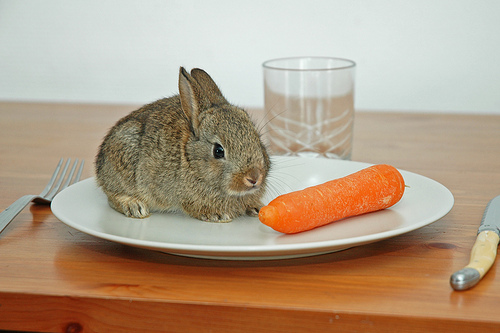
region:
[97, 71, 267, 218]
tiny rabbit on plate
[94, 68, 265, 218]
cute little rabbit on plae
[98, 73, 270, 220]
a really small rabbit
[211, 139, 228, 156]
eye of a rabbit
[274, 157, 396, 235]
a piece of carrot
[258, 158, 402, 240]
carrot on a plate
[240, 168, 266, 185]
nose of a rabbit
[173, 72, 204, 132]
right ear of a rabbit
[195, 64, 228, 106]
left ear of rabbit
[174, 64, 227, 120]
ears of a rabbit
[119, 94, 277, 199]
small bunny on white plate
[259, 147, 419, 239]
small orange carrot on plate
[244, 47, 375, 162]
glass near plate on table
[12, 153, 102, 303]
silver fork on wood table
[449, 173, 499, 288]
silver knife on table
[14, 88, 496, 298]
rectangle wooden table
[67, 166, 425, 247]
shadow on plate cast from bunny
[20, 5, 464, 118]
white wall in background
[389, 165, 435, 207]
small stem of carrot on right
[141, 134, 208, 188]
small brown fur of bunny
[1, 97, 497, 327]
wooden table top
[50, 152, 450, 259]
round white ceramic plate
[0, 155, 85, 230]
silver fork next to plate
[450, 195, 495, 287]
silver knife next to plate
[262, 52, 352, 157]
clear etched glass behind plate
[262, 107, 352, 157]
etching on clear glass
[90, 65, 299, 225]
small brown bunny on plate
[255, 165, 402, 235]
orange carrot on plate next to bunny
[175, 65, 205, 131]
left ear on bunny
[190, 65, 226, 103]
right ear on bunny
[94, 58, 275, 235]
This is a rabbit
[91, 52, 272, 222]
This is a brown rabbit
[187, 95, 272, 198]
Head of a rabbit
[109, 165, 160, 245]
Leg of a rabbit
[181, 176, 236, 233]
Leg of a rabbit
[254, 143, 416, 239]
A piece of carrot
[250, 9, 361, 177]
A grass of water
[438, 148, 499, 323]
This is a knife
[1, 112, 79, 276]
This is a folk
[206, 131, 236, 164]
Eye of a rabbit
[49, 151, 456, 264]
A white round plate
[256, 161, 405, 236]
An orange colored carrot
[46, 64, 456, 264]
A rabbit on a plate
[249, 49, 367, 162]
A glass on the table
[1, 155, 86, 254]
A fork next to the plate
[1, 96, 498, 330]
A brown wooden table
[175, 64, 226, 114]
Two ears on a bunny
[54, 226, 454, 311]
Plate's shadow on the table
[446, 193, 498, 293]
Butter knife on the table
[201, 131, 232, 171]
Black eye on a rabbit